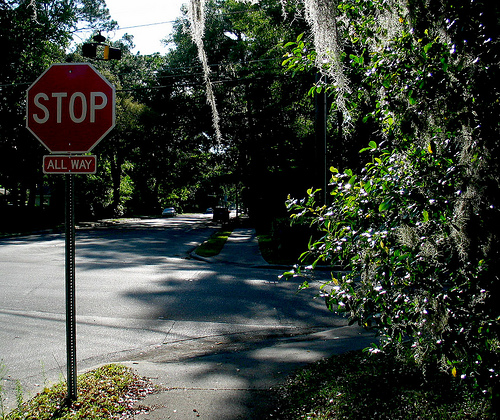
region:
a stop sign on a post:
[13, 66, 117, 201]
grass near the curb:
[88, 357, 152, 403]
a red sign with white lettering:
[36, 152, 105, 177]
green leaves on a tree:
[301, 153, 453, 281]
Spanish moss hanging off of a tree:
[303, 10, 365, 121]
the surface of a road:
[94, 262, 191, 308]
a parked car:
[158, 204, 175, 217]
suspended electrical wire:
[129, 20, 161, 30]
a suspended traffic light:
[79, 27, 139, 59]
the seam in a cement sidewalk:
[147, 377, 252, 398]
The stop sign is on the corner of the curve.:
[26, 71, 128, 415]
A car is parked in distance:
[163, 198, 180, 223]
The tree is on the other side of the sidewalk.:
[310, 159, 464, 373]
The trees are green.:
[136, 55, 219, 210]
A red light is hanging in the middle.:
[73, 25, 148, 68]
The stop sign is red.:
[21, 78, 123, 173]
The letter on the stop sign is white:
[28, 92, 108, 137]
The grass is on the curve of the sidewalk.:
[41, 370, 167, 408]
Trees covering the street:
[122, 30, 423, 225]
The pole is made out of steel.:
[55, 161, 80, 397]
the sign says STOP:
[27, 68, 139, 158]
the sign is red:
[26, 53, 146, 200]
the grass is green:
[39, 391, 130, 418]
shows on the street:
[138, 230, 277, 325]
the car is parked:
[147, 194, 188, 229]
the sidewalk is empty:
[220, 209, 277, 297]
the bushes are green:
[359, 67, 464, 290]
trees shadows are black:
[188, 282, 285, 336]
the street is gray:
[100, 225, 183, 340]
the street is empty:
[83, 224, 277, 335]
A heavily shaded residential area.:
[17, 12, 477, 401]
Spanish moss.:
[276, 10, 431, 141]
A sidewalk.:
[209, 220, 277, 287]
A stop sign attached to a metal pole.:
[13, 47, 134, 412]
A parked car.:
[152, 201, 180, 228]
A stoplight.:
[57, 28, 149, 73]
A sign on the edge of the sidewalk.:
[17, 58, 167, 418]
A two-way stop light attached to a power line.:
[48, 5, 338, 67]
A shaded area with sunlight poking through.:
[76, 12, 458, 273]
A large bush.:
[290, 25, 494, 384]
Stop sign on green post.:
[21, 58, 127, 152]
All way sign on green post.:
[43, 155, 99, 175]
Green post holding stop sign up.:
[63, 172, 81, 407]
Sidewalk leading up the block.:
[218, 221, 264, 261]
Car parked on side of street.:
[160, 206, 182, 222]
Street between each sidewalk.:
[171, 261, 278, 347]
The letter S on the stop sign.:
[32, 90, 52, 132]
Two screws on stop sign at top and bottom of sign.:
[55, 66, 80, 151]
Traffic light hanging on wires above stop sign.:
[88, 26, 134, 70]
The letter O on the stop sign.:
[68, 86, 90, 126]